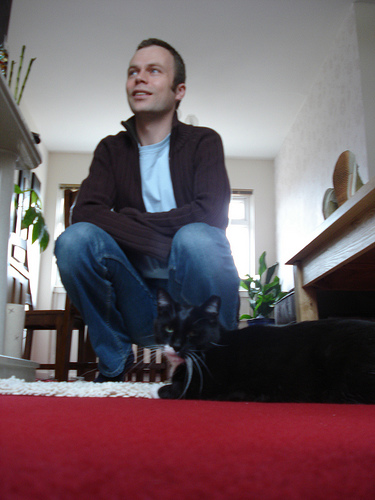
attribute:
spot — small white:
[180, 353, 198, 360]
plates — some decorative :
[310, 148, 360, 218]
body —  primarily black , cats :
[215, 319, 362, 400]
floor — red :
[3, 377, 363, 490]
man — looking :
[53, 32, 248, 370]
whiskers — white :
[179, 339, 232, 394]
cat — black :
[155, 293, 360, 410]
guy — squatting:
[55, 37, 239, 382]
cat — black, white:
[150, 288, 372, 403]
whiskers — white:
[178, 345, 214, 398]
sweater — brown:
[66, 108, 232, 258]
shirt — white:
[131, 137, 178, 278]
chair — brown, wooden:
[19, 186, 98, 380]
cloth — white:
[0, 372, 170, 397]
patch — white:
[160, 342, 179, 356]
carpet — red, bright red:
[0, 393, 372, 497]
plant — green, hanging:
[14, 168, 49, 258]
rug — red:
[2, 393, 374, 497]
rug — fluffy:
[0, 372, 170, 399]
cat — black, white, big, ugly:
[109, 285, 373, 404]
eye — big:
[161, 323, 173, 335]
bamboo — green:
[13, 45, 26, 100]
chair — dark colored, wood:
[23, 243, 89, 380]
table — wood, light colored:
[284, 180, 362, 325]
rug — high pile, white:
[0, 376, 172, 399]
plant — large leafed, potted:
[238, 251, 285, 326]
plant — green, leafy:
[13, 183, 50, 252]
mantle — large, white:
[0, 71, 43, 172]